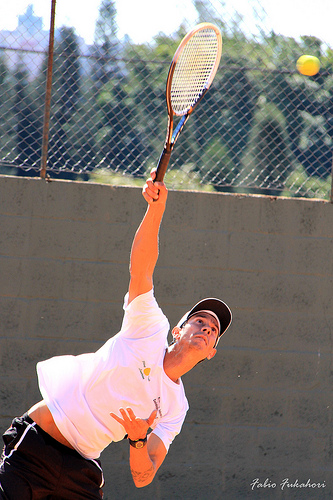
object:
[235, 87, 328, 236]
air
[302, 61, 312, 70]
yellow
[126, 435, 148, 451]
watch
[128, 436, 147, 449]
wrist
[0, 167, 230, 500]
man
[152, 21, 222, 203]
racket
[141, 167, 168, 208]
hand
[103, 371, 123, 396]
white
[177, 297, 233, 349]
cap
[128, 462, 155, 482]
tattoo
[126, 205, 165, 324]
arm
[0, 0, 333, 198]
fence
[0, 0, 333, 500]
court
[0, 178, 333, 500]
wall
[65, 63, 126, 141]
wire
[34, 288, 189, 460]
shirt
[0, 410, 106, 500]
shorts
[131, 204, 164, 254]
forearm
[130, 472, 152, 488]
elbow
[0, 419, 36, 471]
stripe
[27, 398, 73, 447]
midriff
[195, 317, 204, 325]
eyes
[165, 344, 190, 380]
neck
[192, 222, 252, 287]
grey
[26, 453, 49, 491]
black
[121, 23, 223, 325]
swung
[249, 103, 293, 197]
trees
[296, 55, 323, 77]
ball